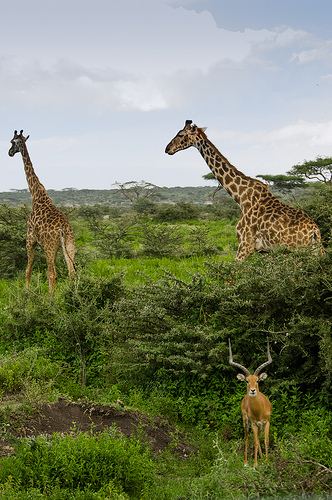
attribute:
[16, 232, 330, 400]
trees — shrub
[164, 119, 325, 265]
giraffe — brown, tan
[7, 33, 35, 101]
clouds — white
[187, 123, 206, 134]
horns — brown, large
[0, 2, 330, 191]
clouds — white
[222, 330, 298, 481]
animal — brown, white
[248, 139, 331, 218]
trees — shrub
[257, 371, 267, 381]
ear — animal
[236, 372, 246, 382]
ear — animal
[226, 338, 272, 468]
animal — antlers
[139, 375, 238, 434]
grass — tall, green, yellow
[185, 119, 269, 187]
neck hair — brown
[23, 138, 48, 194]
neck hair — brown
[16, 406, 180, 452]
dirt — brown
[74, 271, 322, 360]
trees — shrub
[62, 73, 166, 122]
cloud — white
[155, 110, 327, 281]
graffe — tall, brown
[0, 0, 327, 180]
sky — blue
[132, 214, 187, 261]
trees — shrub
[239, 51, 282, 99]
clouds — white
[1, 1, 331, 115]
sky — blue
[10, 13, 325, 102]
sky — blue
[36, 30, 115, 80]
clouds — white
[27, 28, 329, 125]
sky — blue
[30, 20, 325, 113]
sky — blue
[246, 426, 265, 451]
legs — brown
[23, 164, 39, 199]
neck — long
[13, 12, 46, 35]
clouds — white